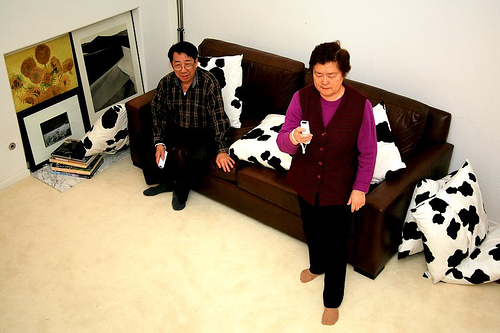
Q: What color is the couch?
A: Brown.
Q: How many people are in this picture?
A: Two.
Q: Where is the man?
A: On the couch.